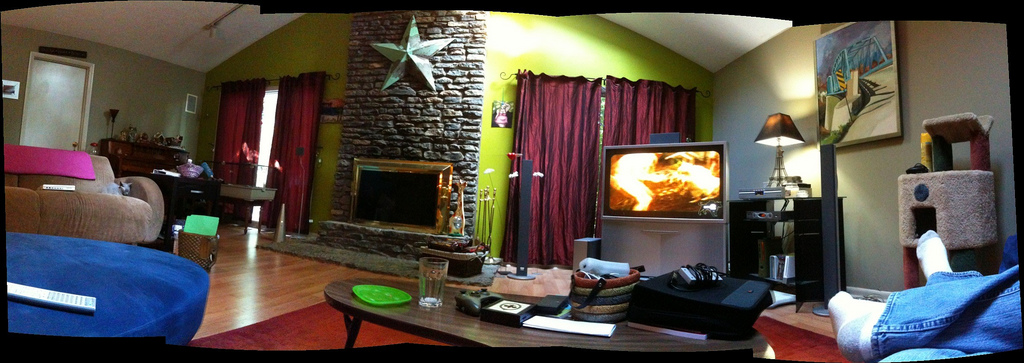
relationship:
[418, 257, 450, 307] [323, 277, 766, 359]
clear glass on coffee table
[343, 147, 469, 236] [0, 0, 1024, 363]
fireplace in living room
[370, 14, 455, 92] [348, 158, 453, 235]
bronze star hanging fireplace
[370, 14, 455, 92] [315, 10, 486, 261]
bronze star on a fireplace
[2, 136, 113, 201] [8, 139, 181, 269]
blanket on couch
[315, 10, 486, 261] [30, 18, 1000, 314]
fireplace in living room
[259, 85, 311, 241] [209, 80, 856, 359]
drapes in living room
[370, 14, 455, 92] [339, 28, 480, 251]
bronze star hanging on fireplace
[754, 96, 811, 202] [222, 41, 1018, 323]
lamp that on living room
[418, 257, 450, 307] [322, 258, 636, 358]
clear glass on coffee table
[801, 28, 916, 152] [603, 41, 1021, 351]
painting on a wall